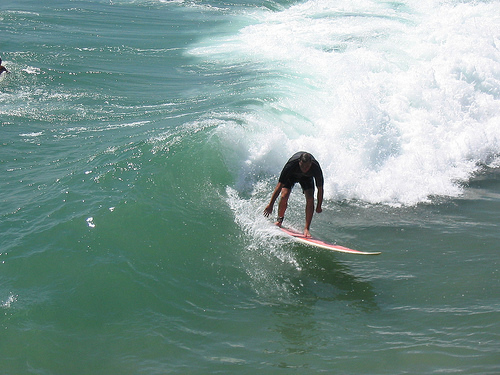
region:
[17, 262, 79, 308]
Small ripples in the water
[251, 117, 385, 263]
Man on a red surfboard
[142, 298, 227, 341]
Small ripples in the water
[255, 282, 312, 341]
Small ripples in the water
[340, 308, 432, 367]
Small ripples in the water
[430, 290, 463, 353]
Small ripples in the water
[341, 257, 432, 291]
Small ripples in the water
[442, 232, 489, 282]
Small ripples in the water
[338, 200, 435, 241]
Small ripples in the water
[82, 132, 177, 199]
Small ripples in the water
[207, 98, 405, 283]
a surfer riding a wave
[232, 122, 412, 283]
a man who is surfing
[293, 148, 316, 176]
the head of a surfer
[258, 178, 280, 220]
the arm of a surfer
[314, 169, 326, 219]
the arm of a surfer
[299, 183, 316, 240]
the leg of a surfer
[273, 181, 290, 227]
the leg of a surfer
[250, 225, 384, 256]
the surfboard of a surfer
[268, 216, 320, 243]
the feet of the surfer on the board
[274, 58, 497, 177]
the waves crashing behind the surfer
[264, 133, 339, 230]
this is is a person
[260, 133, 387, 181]
this is a wave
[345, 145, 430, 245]
this is a wave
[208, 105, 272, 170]
this is a wave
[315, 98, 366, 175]
this is a wave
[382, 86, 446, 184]
this is a wave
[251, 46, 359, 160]
this is a wave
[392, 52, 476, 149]
this is a wave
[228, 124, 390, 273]
Man on a red and white surfboard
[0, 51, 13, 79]
PErson in the water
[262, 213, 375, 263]
Large white and red surfboard in the water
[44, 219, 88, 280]
Small ripples in the water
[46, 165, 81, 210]
Small ripples in the water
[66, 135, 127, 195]
Small ripples in the water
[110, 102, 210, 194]
Small ripples in the water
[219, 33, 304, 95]
Small ripples in the water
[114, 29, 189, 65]
Small ripples in the water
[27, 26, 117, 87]
Small ripples in the water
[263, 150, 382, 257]
Male surfer riding surfboard in ocean.